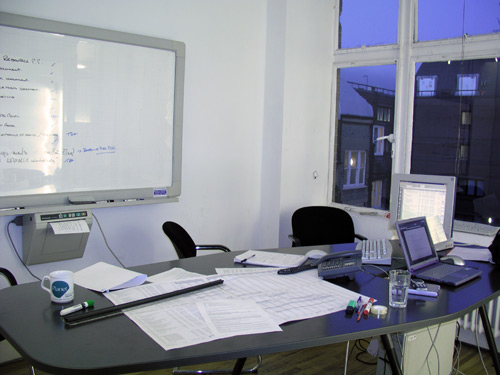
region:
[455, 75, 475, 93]
glass window on the building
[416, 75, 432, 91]
glass window on the building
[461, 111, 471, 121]
glass window on the building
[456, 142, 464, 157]
glass window on the building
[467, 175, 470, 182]
glass window on the building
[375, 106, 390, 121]
glass window on the building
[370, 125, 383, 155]
glass window on the building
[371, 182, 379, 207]
glass window on the building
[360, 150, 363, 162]
glass window on the building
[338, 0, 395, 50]
glass window on the buidling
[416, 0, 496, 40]
glass window on the buidling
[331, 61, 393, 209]
glass window on the buidling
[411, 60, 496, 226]
glass window on the buidling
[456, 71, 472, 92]
glass window on the buidling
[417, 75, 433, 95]
glass window on the buidling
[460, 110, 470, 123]
glass window on the buidling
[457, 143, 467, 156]
glass window on the buidling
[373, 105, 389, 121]
glass window on the buidling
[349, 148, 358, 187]
glass window on the buidling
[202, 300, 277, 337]
a paper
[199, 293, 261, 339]
paper on the table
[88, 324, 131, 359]
a grey table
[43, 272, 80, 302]
a mug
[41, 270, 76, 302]
a mug on the table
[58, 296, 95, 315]
a marker on the table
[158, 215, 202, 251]
a chair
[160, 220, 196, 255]
the chair is black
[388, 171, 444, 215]
a computer monitor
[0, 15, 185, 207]
a white dry erase board on the wall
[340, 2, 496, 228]
a large window in the office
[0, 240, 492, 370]
a large gray table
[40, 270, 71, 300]
white coffee mug with blue writing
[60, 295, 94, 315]
green dry erase marker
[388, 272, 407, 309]
clear glass of water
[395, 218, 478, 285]
laptop computer on the table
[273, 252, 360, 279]
telephone on the table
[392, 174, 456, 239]
gray computer monitor on the table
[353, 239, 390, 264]
desktop computer keyboard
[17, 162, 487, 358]
a long black desk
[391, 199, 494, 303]
an open laptop computer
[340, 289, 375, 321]
several markers on a desk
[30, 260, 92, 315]
a white and blue coffee cup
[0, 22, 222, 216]
a dry erase board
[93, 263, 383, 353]
several papers laying on a desk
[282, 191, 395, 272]
a black office chair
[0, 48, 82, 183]
writing on a dry erase board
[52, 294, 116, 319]
a green dry erase marker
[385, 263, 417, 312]
a glass of water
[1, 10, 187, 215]
A large grey framed white board.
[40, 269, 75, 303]
white and blue coffee mug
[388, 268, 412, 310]
clear glass filled with water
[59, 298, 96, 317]
green marker on top of desk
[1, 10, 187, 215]
whiteboard with writing behind desk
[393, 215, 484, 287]
open laptop on top of desk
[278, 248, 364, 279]
black telephone on top of desk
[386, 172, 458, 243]
grey monitor behind laptop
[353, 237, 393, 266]
grey keyboard behind telephone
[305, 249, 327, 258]
grey mouse on black desk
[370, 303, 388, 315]
clear tape on top of desk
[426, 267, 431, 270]
A key on a keyboard.